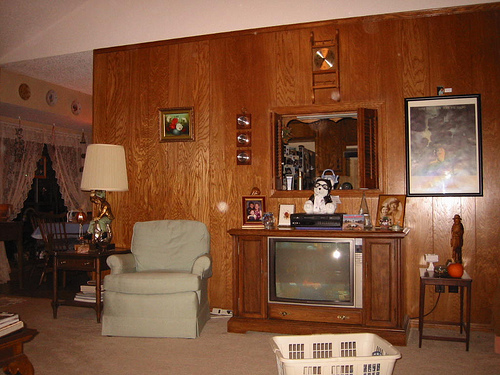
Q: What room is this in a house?
A: Living room.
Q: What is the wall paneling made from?
A: Wood.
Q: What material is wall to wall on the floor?
A: Carpeting.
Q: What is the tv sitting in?
A: A wooden console.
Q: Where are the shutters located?
A: On the wall above the tv.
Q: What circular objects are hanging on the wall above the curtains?
A: Plates.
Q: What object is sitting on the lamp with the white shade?
A: A doll.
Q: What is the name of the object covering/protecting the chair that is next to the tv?
A: A Slipcover.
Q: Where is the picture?
A: On the wall.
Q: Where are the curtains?
A: On the window.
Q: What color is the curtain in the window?
A: White.